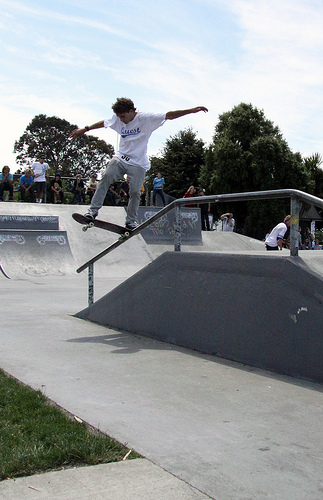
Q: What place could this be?
A: It is a skate park.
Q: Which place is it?
A: It is a skate park.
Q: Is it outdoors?
A: Yes, it is outdoors.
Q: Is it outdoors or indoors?
A: It is outdoors.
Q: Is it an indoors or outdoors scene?
A: It is outdoors.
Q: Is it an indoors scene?
A: No, it is outdoors.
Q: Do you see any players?
A: No, there are no players.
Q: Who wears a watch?
A: The boy wears a watch.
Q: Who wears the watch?
A: The boy wears a watch.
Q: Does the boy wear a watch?
A: Yes, the boy wears a watch.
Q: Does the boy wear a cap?
A: No, the boy wears a watch.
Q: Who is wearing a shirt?
A: The boy is wearing a shirt.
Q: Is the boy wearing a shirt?
A: Yes, the boy is wearing a shirt.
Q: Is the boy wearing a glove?
A: No, the boy is wearing a shirt.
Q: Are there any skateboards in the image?
A: Yes, there is a skateboard.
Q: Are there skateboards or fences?
A: Yes, there is a skateboard.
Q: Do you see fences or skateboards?
A: Yes, there is a skateboard.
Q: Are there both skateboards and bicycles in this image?
A: No, there is a skateboard but no bikes.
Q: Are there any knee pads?
A: No, there are no knee pads.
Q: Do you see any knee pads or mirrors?
A: No, there are no knee pads or mirrors.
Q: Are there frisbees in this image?
A: No, there are no frisbees.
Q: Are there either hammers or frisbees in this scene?
A: No, there are no frisbees or hammers.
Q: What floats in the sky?
A: The clouds float in the sky.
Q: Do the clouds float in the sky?
A: Yes, the clouds float in the sky.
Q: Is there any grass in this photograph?
A: Yes, there is grass.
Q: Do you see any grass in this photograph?
A: Yes, there is grass.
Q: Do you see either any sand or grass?
A: Yes, there is grass.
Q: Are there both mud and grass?
A: No, there is grass but no mud.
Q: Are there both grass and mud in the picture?
A: No, there is grass but no mud.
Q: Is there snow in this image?
A: No, there is no snow.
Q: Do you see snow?
A: No, there is no snow.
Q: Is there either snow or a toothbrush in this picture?
A: No, there are no snow or toothbrushes.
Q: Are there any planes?
A: No, there are no planes.